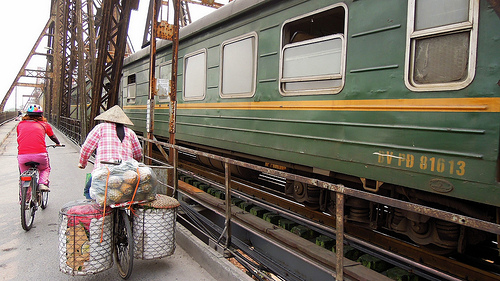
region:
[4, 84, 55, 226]
woman on a bike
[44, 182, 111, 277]
basket on a bike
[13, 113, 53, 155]
woman wearing a pink shirt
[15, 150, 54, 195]
woman wearing pink pants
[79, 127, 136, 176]
woman wearing a plaid shirt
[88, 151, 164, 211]
pineapples in a bag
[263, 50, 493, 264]
train on the railroad tracks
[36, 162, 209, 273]
bike with two baskets on it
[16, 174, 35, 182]
red reflector on a bike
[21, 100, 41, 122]
woman wearing a helmet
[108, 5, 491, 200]
green passenger train with yellow stripe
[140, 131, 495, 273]
railing along side of train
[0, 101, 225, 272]
bicyclists on gray path along train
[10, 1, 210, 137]
slanted beams of bridge supports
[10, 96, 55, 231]
bicycle rider wearing red and pink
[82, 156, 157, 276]
filled plastic bag of produce over bicycle tire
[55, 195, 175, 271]
two filled wire bins on sides of bicycle wheel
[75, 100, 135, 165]
bicyclist wearing woven hat over plaid shirt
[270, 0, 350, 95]
partially open square window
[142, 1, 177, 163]
rusty poles connected to rusty panel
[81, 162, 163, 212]
pineapples in a container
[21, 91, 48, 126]
woman wearing helmet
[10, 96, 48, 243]
woman riding bike on platform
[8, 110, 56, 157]
woman wearing pink shirt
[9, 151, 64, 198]
woman wearing pink pants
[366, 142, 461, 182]
gold paint on a train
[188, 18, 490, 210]
green paint on train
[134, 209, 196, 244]
white basket attched to bike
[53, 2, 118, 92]
rusty beams on bridge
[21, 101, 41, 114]
a helmet on a woman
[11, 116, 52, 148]
a red shirt on a woman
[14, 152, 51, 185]
pink pants on a woman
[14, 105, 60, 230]
a woman riding a bicycle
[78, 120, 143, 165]
a red plaid shirt on a person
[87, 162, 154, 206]
a full bag on the back of a bicycle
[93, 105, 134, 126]
a hat on a person's head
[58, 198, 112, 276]
a large basket on the side of a bicycle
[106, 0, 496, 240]
a green and yellow train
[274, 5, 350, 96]
an open window on a train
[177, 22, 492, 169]
green and yellow train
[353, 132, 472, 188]
yellow ID on train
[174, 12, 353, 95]
small and square windows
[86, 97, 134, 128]
person has grey hat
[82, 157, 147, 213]
clear bag with pineapples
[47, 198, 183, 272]
two baskets on bike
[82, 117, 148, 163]
red and white shirt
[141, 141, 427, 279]
grey rail next to train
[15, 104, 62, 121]
red and blue helmet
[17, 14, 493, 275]
a scene outside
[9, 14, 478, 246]
a scene during the day time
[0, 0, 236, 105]
a white sky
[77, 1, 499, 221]
a green train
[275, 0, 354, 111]
an open window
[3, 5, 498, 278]
a scene at a bridge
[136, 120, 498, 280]
a metal fence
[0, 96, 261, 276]
a gray pavement